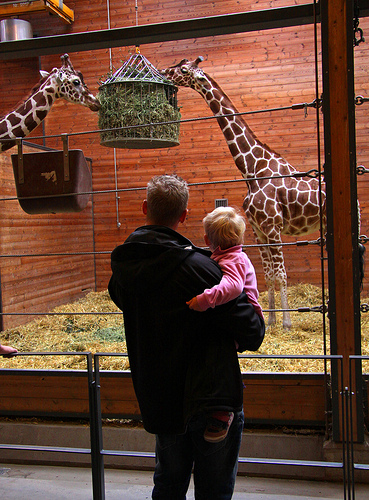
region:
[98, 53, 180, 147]
Cage full of grass hanging from ceiling.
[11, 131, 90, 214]
Brown food container hanging off fence.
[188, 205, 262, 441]
Child who is wearing pink.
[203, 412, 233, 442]
Child has pink shoes.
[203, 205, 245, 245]
Child has blonde hair.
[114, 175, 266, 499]
Man in black holding child.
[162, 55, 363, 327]
Giraffe on the right who is more visible.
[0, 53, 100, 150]
Giraffe on the left.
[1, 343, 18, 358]
Someones hand on the guard railing.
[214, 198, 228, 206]
Vent in the wooden wall.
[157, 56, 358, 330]
Giraffe on the right.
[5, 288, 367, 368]
Straw on the floor of stable.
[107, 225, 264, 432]
The man is wearing a black jacket.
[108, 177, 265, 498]
Man holding a child.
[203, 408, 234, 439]
Child is wearing pink shoe.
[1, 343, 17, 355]
Hand of someone on the railing.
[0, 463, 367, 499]
Floor outside enclosure is cement.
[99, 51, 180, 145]
Basket of hay handing from ceiling.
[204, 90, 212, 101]
brown spot on giraffe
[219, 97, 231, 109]
brown spot on giraffe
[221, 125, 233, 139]
brown spot on giraffe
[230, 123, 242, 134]
brown spot on giraffe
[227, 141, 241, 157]
brown spot on giraffe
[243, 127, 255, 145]
brown spot on giraffe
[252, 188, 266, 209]
brown spot on giraffe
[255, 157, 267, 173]
brown spot on giraffe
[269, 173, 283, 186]
brown spot on giraffe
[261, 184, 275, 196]
brown spot on giraffe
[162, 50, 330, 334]
large giraffe reaching for food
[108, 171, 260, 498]
man wearing a black coat holding a child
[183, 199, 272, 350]
blonde child wearing a pink coat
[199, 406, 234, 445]
child's shoe with a pink strap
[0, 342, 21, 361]
person's hand on the railing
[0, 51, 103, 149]
head and neck of a giraffe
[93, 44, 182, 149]
giraffe feeder filled with hay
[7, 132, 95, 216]
brown food bucket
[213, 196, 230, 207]
small metal vent on the wall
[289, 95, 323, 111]
circular metal bolt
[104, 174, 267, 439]
a man is holding a baby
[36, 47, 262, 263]
the man and baby are watching giraffes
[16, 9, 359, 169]
the giraffes are eating from a feeder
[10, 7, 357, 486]
the giraffes are in an enclosure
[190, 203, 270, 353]
the baby has a pink fleece sweater on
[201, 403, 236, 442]
pink and black sneakers are on the girl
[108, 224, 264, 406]
the man has a black hoodie jacket on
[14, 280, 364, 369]
hay is on the bottom of the cage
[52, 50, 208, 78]
the giraffes have black and white furry horns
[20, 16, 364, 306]
the walls of the enclosure are wooden